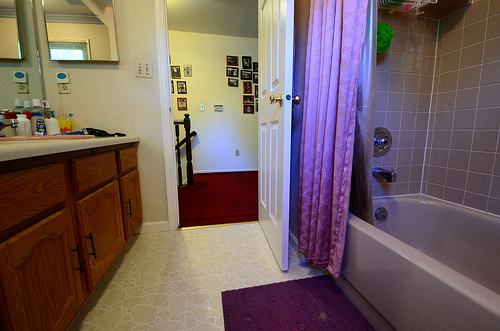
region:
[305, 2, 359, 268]
purple shower curtain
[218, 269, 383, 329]
purple rug next to bathtub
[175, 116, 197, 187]
black railing of the stairs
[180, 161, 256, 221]
red carpet in the hallway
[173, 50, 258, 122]
picture frames hung on the wall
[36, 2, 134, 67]
mirror above the countertop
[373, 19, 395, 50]
green bath sponge hanging in the shower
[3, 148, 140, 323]
wood cabinets in the bathroom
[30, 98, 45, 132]
mouthwash bottle on the counter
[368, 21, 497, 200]
tiled walls in the shower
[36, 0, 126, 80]
reflection of window in mirror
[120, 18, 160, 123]
light switch on white wall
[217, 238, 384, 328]
Purple rug on bathroom floor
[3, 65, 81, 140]
grooming products on counter top.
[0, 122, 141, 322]
Cabinets made of brown wood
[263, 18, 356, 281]
shower curtain behind door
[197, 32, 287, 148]
pictures hung on white wall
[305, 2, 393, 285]
a purple shower curtain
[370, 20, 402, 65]
a green scrunchie for cleaning self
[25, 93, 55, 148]
a bottle of mouth wash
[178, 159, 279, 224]
red carpet in the hall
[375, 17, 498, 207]
tan tile on wall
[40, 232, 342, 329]
white tile on floor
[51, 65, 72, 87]
a blue and white object plugged in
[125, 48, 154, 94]
a double light switch on wall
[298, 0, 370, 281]
Purple shower curtain next to bathtub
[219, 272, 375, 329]
Purple bath mat in front of bathtub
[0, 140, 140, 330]
Wooden vanity with white counter top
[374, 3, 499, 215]
Beige tiles with white caulking around bat tub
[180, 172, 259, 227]
Red carpet outside of bathroom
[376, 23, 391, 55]
Green loofah hanging from shelf inside shower area of bathtub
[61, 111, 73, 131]
Yellow and red cup with toothbrush in it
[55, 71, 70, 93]
White and blue night light plugged into bathroom outlet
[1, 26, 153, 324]
view in a washroom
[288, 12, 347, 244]
curtainns are pink in vcolor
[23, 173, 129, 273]
the cabins are wooden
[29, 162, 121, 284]
cabins are brown in color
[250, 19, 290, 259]
the door is whit 9n color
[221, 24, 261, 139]
posters are on the wall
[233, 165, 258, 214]
the floor is wooden